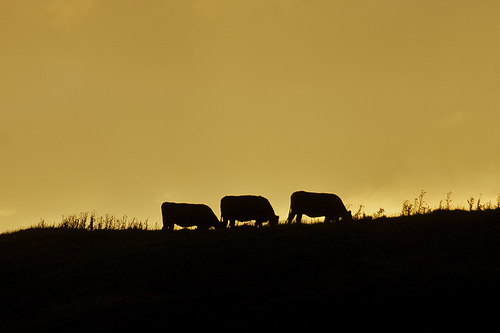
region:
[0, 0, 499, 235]
a large patch of golden sky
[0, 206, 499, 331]
a grassy hill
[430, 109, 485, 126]
a small cloud in the sky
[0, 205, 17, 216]
a small cloud in the sky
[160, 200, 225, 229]
a cow on the left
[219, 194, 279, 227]
a cow in the center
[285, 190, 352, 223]
a cow on the right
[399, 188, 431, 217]
a small group of plants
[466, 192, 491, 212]
small group of plants on the far right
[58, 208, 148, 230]
larger group of plants on the left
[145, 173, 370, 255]
Silhouette of three animals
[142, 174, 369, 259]
three animals are grazing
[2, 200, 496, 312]
Silhouette of a grassy hill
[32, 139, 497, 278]
The sun is rising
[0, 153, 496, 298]
The sun is setting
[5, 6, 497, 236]
The sky is cloudy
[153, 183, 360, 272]
Three animals next to each other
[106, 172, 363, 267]
the animals are eating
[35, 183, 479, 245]
the grass is tall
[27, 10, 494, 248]
the sky is orange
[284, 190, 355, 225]
A grazing cow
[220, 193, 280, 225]
A grazing cow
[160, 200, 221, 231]
A grazing cow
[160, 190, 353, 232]
A trio of cows grazing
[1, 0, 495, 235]
A cloudy yellow sky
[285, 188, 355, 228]
the silhouette of a cow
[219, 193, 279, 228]
the silhouette of a cow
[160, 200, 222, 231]
the silhouette of a cow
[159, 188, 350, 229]
the silhouette of a trio of cows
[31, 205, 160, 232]
A patch of tall grass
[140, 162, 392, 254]
three cows grazing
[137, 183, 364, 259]
three cows standing in field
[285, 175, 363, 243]
black cow grazing in field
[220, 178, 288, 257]
black cow grazing in field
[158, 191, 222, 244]
black cow grazing in field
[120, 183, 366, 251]
three cows in a line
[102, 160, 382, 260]
cows in a line on a field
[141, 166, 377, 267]
three cows grazing together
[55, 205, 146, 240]
plants growing on field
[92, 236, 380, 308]
black field with plants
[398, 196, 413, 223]
grasses in the field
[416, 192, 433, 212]
grasses in the field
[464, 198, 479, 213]
grasses in the field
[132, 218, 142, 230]
grasses in the field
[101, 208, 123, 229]
grasses in the field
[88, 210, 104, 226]
grasses in the field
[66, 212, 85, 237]
grasses in the field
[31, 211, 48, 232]
grasses in the field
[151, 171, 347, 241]
cows grazing in the field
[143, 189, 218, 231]
cow at the back